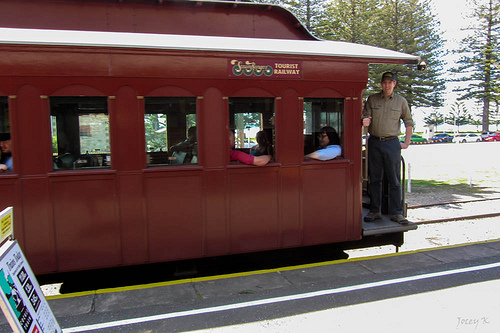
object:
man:
[227, 131, 276, 167]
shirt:
[232, 149, 256, 164]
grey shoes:
[364, 212, 409, 225]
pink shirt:
[229, 148, 254, 165]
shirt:
[361, 91, 414, 137]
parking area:
[398, 131, 497, 145]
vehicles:
[400, 133, 499, 145]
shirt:
[316, 144, 341, 161]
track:
[413, 198, 498, 226]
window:
[0, 94, 15, 179]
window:
[45, 93, 117, 173]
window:
[140, 92, 201, 169]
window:
[224, 94, 279, 166]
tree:
[447, 0, 499, 131]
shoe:
[364, 210, 382, 222]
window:
[304, 97, 344, 159]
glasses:
[316, 133, 328, 138]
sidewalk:
[97, 292, 251, 332]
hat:
[382, 71, 395, 81]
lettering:
[385, 73, 392, 77]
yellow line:
[132, 278, 202, 294]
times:
[7, 262, 43, 322]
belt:
[367, 136, 398, 141]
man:
[361, 69, 415, 226]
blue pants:
[368, 137, 403, 215]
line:
[43, 237, 500, 300]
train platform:
[72, 264, 474, 331]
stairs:
[362, 185, 382, 208]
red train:
[5, 0, 419, 284]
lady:
[304, 125, 341, 163]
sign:
[0, 239, 65, 333]